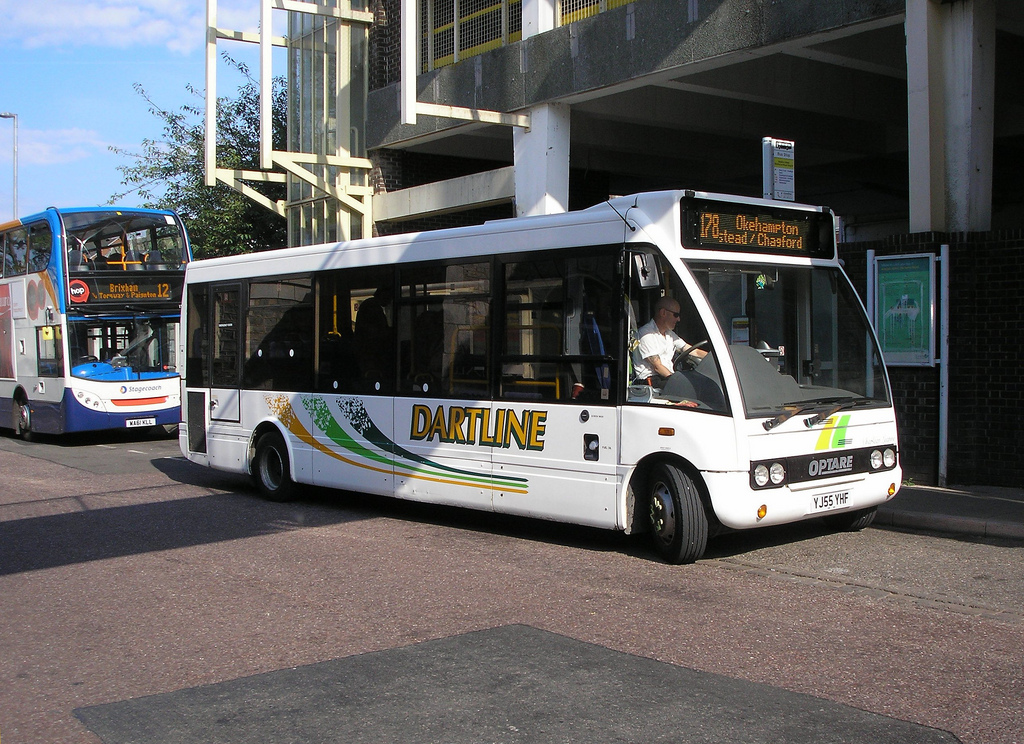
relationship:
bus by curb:
[163, 179, 915, 560] [875, 467, 1019, 553]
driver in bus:
[628, 290, 711, 386] [163, 179, 915, 560]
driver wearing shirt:
[628, 290, 711, 386] [632, 319, 691, 378]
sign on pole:
[870, 247, 934, 361] [861, 240, 881, 393]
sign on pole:
[870, 247, 934, 361] [936, 238, 955, 485]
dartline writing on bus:
[406, 394, 557, 456] [163, 179, 915, 560]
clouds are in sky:
[3, 112, 129, 174] [6, 7, 277, 203]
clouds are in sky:
[12, 9, 213, 68] [6, 7, 277, 203]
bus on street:
[3, 200, 201, 448] [1, 438, 1023, 741]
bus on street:
[163, 179, 915, 560] [1, 438, 1023, 741]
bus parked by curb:
[3, 200, 201, 448] [875, 493, 1022, 554]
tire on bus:
[629, 454, 715, 562] [163, 179, 915, 560]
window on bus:
[169, 236, 636, 407] [163, 179, 915, 560]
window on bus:
[672, 243, 902, 421] [163, 179, 915, 560]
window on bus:
[613, 243, 742, 421] [163, 179, 915, 560]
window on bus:
[485, 237, 636, 402] [163, 179, 915, 560]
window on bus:
[181, 264, 255, 384] [163, 179, 915, 560]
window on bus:
[35, 315, 63, 383] [3, 200, 201, 448]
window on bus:
[242, 267, 319, 392] [163, 179, 915, 560]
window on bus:
[309, 254, 414, 394] [163, 179, 915, 560]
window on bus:
[406, 249, 510, 408] [163, 179, 915, 560]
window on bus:
[53, 206, 191, 270] [0, 206, 192, 440]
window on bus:
[57, 304, 192, 376] [3, 200, 201, 448]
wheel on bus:
[249, 427, 298, 497] [163, 179, 915, 560]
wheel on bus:
[637, 447, 712, 563] [163, 179, 915, 560]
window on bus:
[681, 243, 892, 421] [163, 179, 915, 560]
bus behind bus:
[3, 200, 201, 448] [163, 179, 915, 560]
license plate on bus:
[803, 481, 856, 512] [163, 179, 915, 560]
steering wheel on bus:
[671, 332, 710, 374] [163, 179, 915, 560]